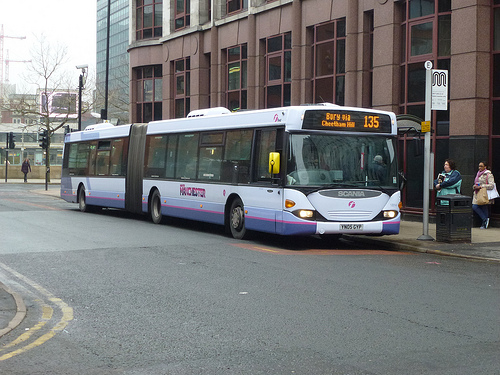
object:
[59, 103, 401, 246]
bus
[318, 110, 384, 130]
readout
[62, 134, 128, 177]
windows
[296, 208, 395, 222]
headlights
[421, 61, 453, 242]
signpost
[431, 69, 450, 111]
banner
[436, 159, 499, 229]
people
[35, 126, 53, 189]
stoplights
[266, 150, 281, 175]
mirror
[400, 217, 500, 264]
sidewalk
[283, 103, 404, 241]
front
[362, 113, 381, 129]
numbers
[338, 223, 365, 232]
license plate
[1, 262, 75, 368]
line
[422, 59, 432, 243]
pole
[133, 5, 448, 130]
windows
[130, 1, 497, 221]
building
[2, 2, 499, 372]
city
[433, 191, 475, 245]
trash receptacle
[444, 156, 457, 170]
hair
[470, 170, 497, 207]
jacket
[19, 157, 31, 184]
woman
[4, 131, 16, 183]
traffic light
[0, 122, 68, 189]
distance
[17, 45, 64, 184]
tree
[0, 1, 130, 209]
background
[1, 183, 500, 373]
street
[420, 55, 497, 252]
bus stop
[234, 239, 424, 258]
marking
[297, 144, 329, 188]
driver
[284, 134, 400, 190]
windshield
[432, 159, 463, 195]
person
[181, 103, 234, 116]
vents